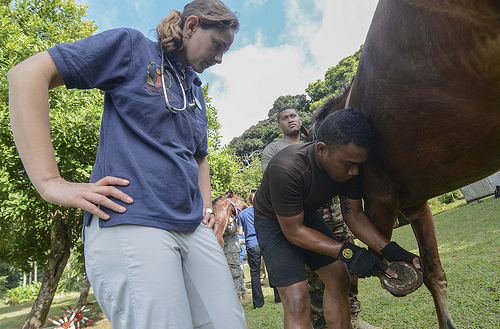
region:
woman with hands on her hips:
[15, 0, 232, 327]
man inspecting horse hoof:
[254, 114, 423, 324]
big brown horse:
[322, 0, 492, 326]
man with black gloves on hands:
[336, 233, 425, 297]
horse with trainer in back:
[210, 180, 270, 295]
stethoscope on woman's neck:
[156, 32, 210, 115]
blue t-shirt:
[60, 32, 217, 225]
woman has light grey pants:
[91, 216, 237, 326]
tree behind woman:
[2, 2, 128, 324]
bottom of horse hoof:
[376, 255, 423, 292]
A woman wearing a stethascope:
[6, 1, 249, 327]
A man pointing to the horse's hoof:
[202, 116, 433, 322]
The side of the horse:
[342, 52, 499, 214]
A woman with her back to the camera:
[237, 189, 284, 311]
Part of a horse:
[209, 188, 249, 239]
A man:
[262, 99, 313, 164]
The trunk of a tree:
[15, 221, 78, 327]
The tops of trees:
[220, 47, 364, 159]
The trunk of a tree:
[74, 268, 95, 312]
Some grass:
[447, 208, 498, 310]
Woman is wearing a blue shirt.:
[88, 69, 211, 223]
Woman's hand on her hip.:
[9, 32, 149, 246]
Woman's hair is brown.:
[156, 10, 189, 52]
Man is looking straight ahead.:
[263, 95, 312, 147]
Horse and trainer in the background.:
[211, 172, 259, 249]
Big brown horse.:
[379, 0, 496, 185]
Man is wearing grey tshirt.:
[249, 139, 288, 159]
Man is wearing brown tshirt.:
[261, 155, 321, 215]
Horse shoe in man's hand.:
[376, 262, 423, 296]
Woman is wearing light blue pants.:
[86, 227, 255, 327]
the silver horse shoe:
[364, 253, 432, 300]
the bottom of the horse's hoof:
[385, 255, 447, 303]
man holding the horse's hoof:
[333, 235, 453, 311]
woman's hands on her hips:
[28, 142, 254, 260]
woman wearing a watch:
[204, 201, 221, 225]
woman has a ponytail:
[148, 7, 224, 47]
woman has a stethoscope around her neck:
[153, 52, 214, 131]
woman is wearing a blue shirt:
[85, 32, 264, 260]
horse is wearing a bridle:
[218, 182, 259, 224]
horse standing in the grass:
[377, 231, 498, 318]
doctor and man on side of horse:
[15, 10, 477, 308]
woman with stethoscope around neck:
[40, 5, 235, 262]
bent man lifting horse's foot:
[250, 110, 430, 310]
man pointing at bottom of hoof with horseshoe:
[270, 115, 442, 295]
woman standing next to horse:
[210, 140, 285, 305]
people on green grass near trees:
[15, 32, 482, 312]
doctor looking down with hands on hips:
[15, 5, 255, 281]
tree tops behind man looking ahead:
[237, 45, 352, 145]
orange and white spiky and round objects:
[35, 290, 97, 325]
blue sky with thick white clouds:
[103, 6, 381, 121]